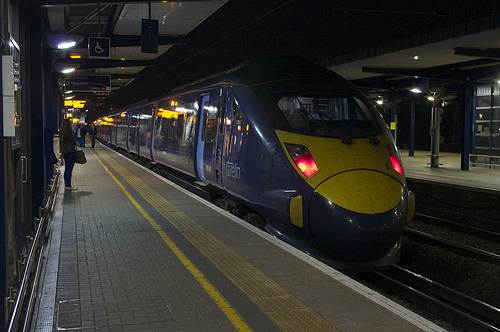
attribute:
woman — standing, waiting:
[60, 115, 90, 191]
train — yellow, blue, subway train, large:
[91, 64, 414, 263]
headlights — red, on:
[298, 152, 407, 183]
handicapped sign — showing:
[91, 37, 116, 62]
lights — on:
[54, 38, 80, 86]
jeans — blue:
[61, 155, 79, 188]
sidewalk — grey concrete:
[79, 134, 222, 220]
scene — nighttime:
[1, 8, 499, 332]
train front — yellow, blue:
[237, 69, 424, 249]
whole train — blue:
[91, 68, 276, 214]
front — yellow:
[277, 129, 413, 213]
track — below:
[360, 207, 498, 313]